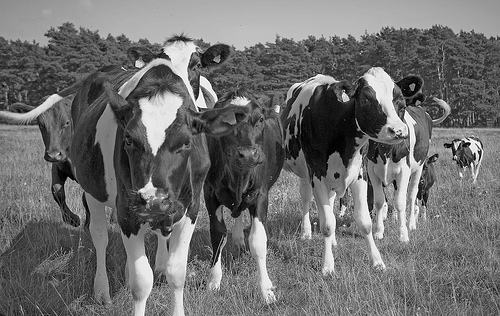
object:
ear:
[183, 106, 248, 139]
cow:
[198, 89, 284, 307]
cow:
[124, 34, 232, 110]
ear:
[203, 43, 233, 71]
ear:
[326, 79, 358, 103]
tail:
[0, 84, 82, 128]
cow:
[67, 57, 211, 316]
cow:
[370, 96, 452, 242]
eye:
[178, 137, 191, 152]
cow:
[62, 58, 248, 316]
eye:
[123, 136, 137, 151]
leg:
[311, 189, 338, 279]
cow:
[279, 72, 425, 274]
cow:
[442, 134, 484, 185]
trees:
[0, 20, 498, 123]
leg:
[246, 178, 280, 305]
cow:
[206, 88, 289, 305]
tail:
[428, 95, 452, 126]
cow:
[366, 105, 434, 244]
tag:
[130, 59, 145, 69]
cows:
[0, 34, 483, 315]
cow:
[280, 73, 409, 276]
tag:
[212, 53, 224, 65]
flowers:
[428, 196, 464, 223]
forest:
[1, 20, 499, 130]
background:
[0, 24, 497, 123]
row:
[2, 18, 496, 130]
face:
[218, 102, 267, 167]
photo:
[0, 2, 496, 314]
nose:
[134, 187, 174, 215]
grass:
[0, 126, 499, 316]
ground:
[0, 124, 499, 316]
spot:
[135, 164, 162, 214]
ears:
[102, 81, 251, 139]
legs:
[294, 181, 430, 279]